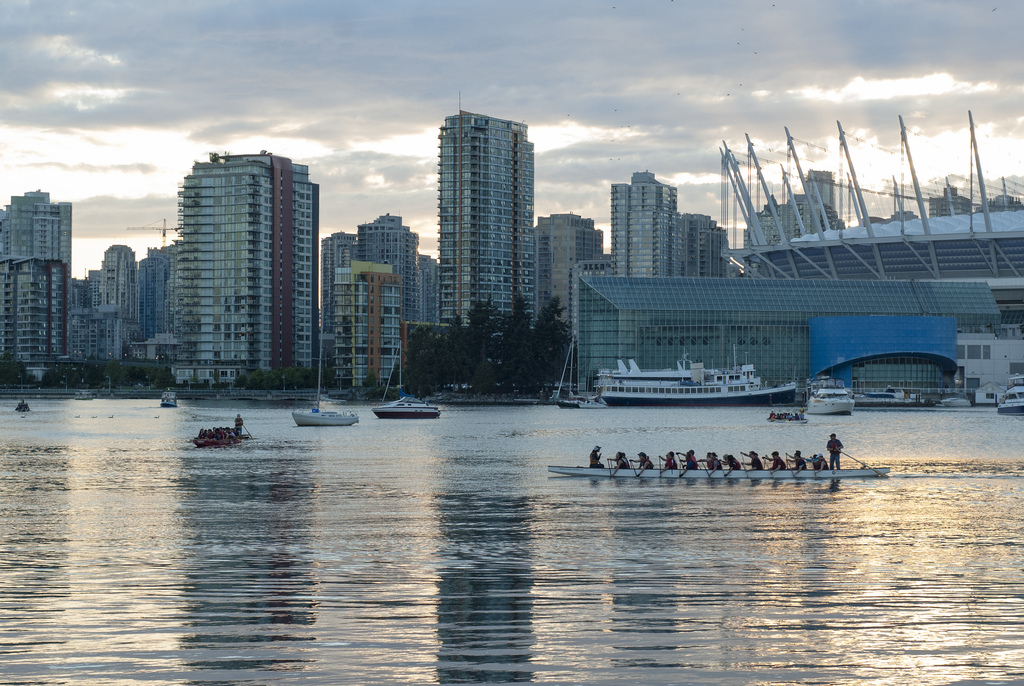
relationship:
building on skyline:
[0, 105, 1024, 394] [6, 91, 1022, 293]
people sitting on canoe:
[568, 425, 843, 477] [545, 466, 898, 492]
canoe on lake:
[538, 455, 910, 484] [6, 395, 1007, 681]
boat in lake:
[289, 395, 363, 447] [6, 395, 1007, 681]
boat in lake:
[560, 332, 783, 417] [6, 395, 1007, 681]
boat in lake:
[378, 395, 441, 428] [6, 395, 1007, 681]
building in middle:
[0, 105, 1024, 394] [341, 122, 691, 427]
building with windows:
[291, 199, 464, 439] [347, 275, 408, 390]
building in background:
[0, 105, 1024, 394] [56, 150, 813, 429]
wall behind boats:
[781, 307, 993, 357] [589, 336, 966, 438]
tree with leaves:
[442, 297, 551, 360] [440, 299, 562, 360]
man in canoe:
[814, 387, 879, 522] [525, 431, 911, 494]